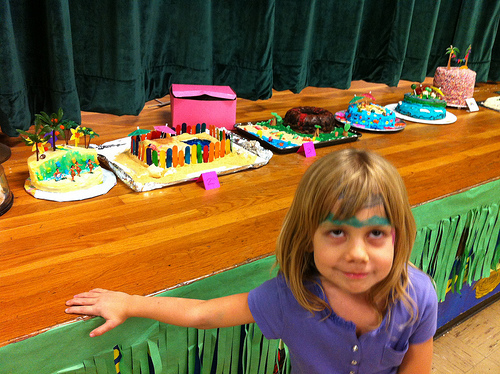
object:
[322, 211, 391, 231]
paint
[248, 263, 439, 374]
purple shirt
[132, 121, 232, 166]
fence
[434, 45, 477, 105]
cakes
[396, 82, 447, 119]
cakes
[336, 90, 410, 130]
cakes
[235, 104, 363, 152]
cakes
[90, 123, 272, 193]
cakes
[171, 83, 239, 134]
box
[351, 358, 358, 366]
button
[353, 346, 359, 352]
button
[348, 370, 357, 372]
button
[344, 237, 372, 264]
nose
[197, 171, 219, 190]
note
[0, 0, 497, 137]
curtain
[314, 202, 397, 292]
face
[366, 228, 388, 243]
left eye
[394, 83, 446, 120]
blue cake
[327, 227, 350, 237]
eyes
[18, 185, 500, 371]
paper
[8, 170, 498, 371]
fringe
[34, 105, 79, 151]
trees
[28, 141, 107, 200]
cake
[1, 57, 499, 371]
table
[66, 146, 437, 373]
child